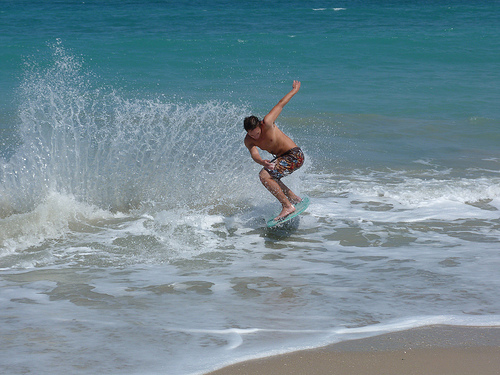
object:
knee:
[258, 167, 273, 185]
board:
[267, 196, 309, 228]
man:
[243, 78, 305, 220]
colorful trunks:
[264, 148, 305, 179]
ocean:
[1, 1, 497, 374]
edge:
[194, 318, 499, 374]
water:
[2, 1, 497, 372]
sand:
[205, 325, 497, 374]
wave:
[3, 36, 500, 256]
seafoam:
[2, 162, 499, 373]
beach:
[204, 320, 499, 373]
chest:
[253, 129, 276, 148]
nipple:
[268, 137, 275, 142]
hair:
[242, 115, 264, 132]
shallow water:
[2, 166, 497, 374]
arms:
[246, 140, 263, 164]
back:
[273, 125, 298, 147]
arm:
[262, 88, 296, 123]